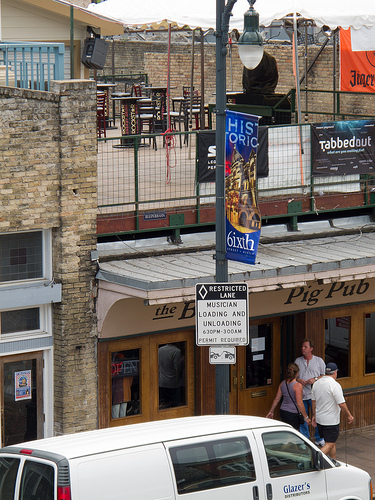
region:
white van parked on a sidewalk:
[6, 406, 311, 499]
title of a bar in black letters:
[283, 281, 369, 306]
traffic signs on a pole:
[188, 268, 254, 368]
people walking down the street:
[264, 336, 359, 439]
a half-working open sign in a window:
[106, 357, 144, 382]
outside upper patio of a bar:
[87, 62, 345, 172]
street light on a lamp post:
[230, 4, 272, 69]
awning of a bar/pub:
[104, 253, 367, 300]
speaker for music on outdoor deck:
[73, 28, 112, 72]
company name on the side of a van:
[277, 482, 325, 498]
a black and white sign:
[191, 280, 252, 346]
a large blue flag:
[224, 108, 271, 266]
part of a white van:
[0, 416, 372, 499]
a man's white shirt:
[310, 376, 346, 427]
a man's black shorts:
[316, 423, 342, 440]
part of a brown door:
[242, 316, 284, 418]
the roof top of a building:
[94, 88, 356, 202]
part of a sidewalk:
[327, 425, 374, 472]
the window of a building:
[0, 309, 38, 333]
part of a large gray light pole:
[212, 0, 264, 413]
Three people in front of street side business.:
[265, 334, 355, 485]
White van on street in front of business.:
[1, 405, 370, 498]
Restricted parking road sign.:
[197, 283, 247, 364]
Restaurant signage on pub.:
[281, 280, 374, 307]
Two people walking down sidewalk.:
[262, 361, 355, 478]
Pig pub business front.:
[93, 251, 373, 447]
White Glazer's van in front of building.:
[0, 414, 374, 499]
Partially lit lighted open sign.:
[105, 347, 143, 418]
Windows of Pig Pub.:
[98, 340, 194, 418]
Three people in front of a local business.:
[265, 337, 356, 468]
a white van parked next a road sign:
[5, 276, 360, 498]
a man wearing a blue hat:
[315, 357, 342, 380]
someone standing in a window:
[104, 354, 137, 422]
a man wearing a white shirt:
[308, 373, 348, 433]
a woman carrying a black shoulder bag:
[277, 363, 304, 429]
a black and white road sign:
[191, 283, 253, 349]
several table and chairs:
[68, 74, 238, 138]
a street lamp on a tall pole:
[196, 2, 268, 487]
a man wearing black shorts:
[309, 412, 343, 446]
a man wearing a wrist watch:
[310, 371, 322, 384]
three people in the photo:
[272, 327, 355, 405]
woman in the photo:
[272, 359, 307, 402]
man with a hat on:
[312, 362, 348, 407]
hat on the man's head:
[317, 358, 343, 380]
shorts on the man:
[314, 416, 347, 449]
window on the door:
[238, 321, 287, 382]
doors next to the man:
[221, 336, 275, 411]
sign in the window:
[103, 346, 151, 389]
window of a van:
[261, 434, 312, 478]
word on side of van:
[275, 470, 321, 498]